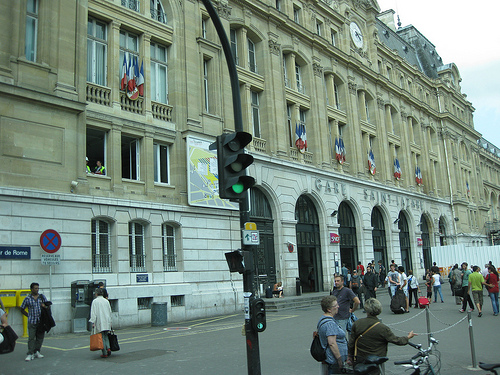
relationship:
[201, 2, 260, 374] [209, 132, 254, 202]
pole has a light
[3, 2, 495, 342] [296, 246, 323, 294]
building has a doorway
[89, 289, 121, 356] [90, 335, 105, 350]
woman has a bag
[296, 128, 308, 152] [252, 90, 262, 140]
flag in front of a window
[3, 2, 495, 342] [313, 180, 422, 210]
building has words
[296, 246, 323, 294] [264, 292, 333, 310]
doorway has stairs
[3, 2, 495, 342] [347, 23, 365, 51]
building has a clock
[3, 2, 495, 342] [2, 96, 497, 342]
building has a bottom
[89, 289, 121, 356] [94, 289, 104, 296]
woman has a head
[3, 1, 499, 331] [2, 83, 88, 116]
wall has an edge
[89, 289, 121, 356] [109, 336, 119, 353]
woman has a purse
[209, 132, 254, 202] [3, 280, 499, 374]
light on street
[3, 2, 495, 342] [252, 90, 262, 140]
building has a window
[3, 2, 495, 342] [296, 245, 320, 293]
building has a door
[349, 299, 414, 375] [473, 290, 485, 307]
person has on a shirt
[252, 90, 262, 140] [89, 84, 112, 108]
window has a balcony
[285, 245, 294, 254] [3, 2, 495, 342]
map hanging on building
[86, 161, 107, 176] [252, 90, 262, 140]
worker in window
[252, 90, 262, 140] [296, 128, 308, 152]
window has a flag